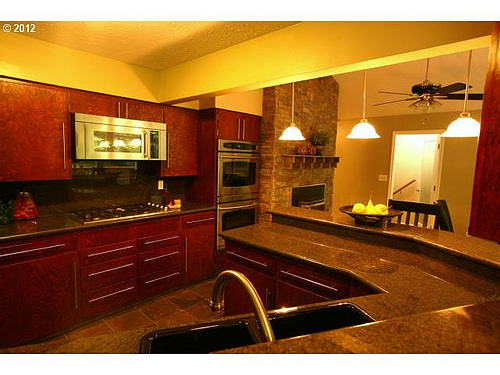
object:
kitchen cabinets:
[1, 239, 75, 349]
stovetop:
[74, 200, 173, 220]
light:
[409, 94, 444, 110]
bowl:
[338, 204, 404, 227]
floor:
[93, 301, 172, 324]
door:
[391, 133, 444, 224]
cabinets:
[82, 238, 139, 316]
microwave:
[85, 123, 161, 159]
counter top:
[376, 328, 444, 349]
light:
[439, 115, 481, 138]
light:
[346, 122, 381, 139]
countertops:
[479, 329, 500, 350]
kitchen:
[2, 21, 499, 352]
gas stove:
[72, 200, 169, 223]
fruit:
[352, 202, 366, 213]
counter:
[218, 203, 500, 294]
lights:
[400, 137, 409, 145]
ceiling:
[212, 45, 484, 101]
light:
[279, 123, 305, 140]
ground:
[127, 300, 174, 327]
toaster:
[12, 191, 40, 222]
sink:
[136, 301, 379, 354]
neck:
[227, 271, 276, 336]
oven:
[218, 152, 260, 203]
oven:
[216, 203, 259, 251]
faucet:
[205, 267, 275, 344]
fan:
[373, 80, 483, 111]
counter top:
[403, 227, 455, 241]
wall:
[267, 159, 284, 207]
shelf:
[283, 154, 341, 171]